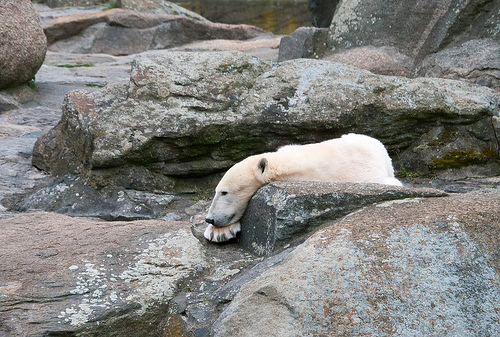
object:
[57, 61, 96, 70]
green moss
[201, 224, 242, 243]
claw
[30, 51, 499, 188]
large rock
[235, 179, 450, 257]
rock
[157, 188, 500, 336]
rock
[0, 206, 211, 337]
rock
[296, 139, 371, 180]
loin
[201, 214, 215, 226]
nose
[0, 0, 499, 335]
photo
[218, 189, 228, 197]
eye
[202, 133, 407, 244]
bear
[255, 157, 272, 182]
ear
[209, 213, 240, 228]
mouth